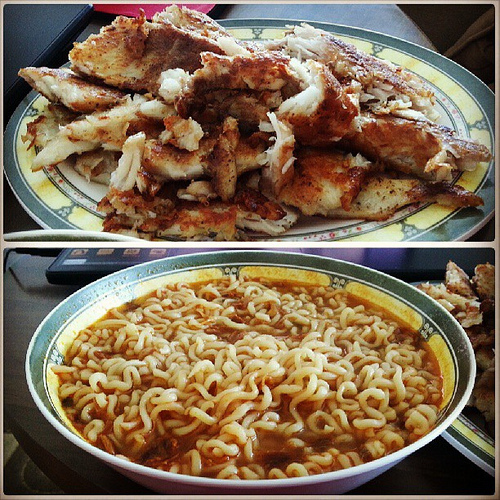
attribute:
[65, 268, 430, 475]
noodles — curly, ramen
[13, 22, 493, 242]
plate — green, yellow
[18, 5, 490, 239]
food — yellow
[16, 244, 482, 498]
bowl — circular, yellow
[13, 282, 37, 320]
table — wooden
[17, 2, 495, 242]
fish — grilled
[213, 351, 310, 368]
noodles — ramen noodles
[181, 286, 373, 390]
noodles — green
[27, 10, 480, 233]
meat — cooked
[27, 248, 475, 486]
pattern — green, yellow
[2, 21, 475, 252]
plate — green